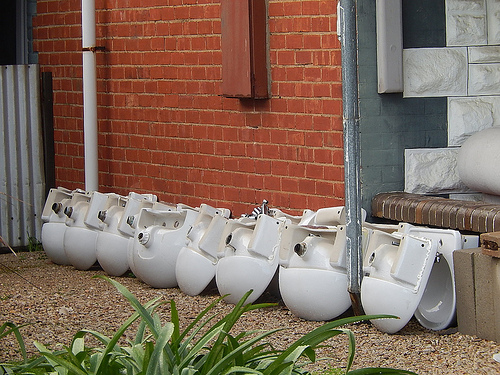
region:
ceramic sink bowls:
[40, 185, 481, 334]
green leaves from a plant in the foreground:
[0, 277, 420, 374]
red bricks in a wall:
[95, 101, 340, 186]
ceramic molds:
[401, 0, 497, 195]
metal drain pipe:
[335, 0, 361, 316]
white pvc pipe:
[80, 0, 97, 190]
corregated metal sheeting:
[0, 63, 51, 246]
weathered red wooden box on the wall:
[216, 0, 266, 100]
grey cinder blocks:
[450, 230, 495, 335]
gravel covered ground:
[357, 333, 497, 371]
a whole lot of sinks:
[39, 173, 483, 343]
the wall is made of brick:
[153, 135, 270, 191]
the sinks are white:
[68, 189, 451, 341]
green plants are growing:
[33, 316, 375, 373]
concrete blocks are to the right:
[437, 238, 499, 330]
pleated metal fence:
[2, 62, 58, 265]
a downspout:
[332, 6, 364, 330]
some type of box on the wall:
[203, 5, 303, 110]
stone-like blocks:
[401, 8, 497, 122]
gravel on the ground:
[41, 282, 186, 357]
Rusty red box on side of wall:
[218, 5, 268, 98]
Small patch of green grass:
[8, 276, 399, 373]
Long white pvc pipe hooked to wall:
[80, 2, 102, 190]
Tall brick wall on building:
[31, 3, 345, 213]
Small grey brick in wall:
[357, 96, 380, 115]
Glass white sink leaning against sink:
[362, 229, 436, 334]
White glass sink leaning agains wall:
[98, 190, 154, 275]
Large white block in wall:
[401, 48, 467, 94]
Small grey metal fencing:
[1, 64, 46, 252]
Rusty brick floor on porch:
[376, 195, 498, 227]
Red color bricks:
[140, 40, 199, 156]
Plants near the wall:
[47, 335, 310, 367]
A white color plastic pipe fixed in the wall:
[74, 19, 114, 157]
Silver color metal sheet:
[8, 68, 30, 197]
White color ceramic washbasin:
[57, 193, 324, 286]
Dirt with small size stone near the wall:
[21, 268, 105, 321]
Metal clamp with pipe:
[78, 43, 103, 59]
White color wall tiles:
[418, 23, 495, 97]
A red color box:
[219, 3, 264, 101]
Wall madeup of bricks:
[41, 4, 320, 169]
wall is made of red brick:
[35, 4, 342, 216]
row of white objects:
[36, 177, 468, 337]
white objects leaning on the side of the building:
[37, 167, 467, 335]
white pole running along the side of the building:
[69, 1, 115, 197]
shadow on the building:
[41, 68, 62, 186]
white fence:
[1, 65, 58, 250]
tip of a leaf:
[390, 309, 404, 326]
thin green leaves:
[1, 268, 435, 374]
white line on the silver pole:
[341, 120, 353, 170]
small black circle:
[289, 236, 307, 257]